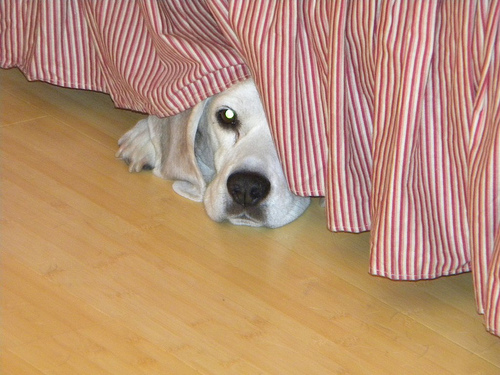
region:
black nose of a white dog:
[224, 166, 268, 206]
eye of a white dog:
[217, 104, 237, 125]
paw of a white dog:
[106, 114, 160, 179]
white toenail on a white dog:
[132, 155, 144, 174]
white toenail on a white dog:
[127, 158, 134, 174]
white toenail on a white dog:
[112, 142, 126, 159]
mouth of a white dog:
[221, 201, 270, 233]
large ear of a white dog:
[145, 95, 215, 207]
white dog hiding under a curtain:
[113, 58, 321, 233]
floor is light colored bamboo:
[2, 74, 497, 369]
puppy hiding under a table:
[119, 72, 321, 230]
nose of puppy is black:
[223, 160, 270, 210]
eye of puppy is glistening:
[213, 103, 244, 134]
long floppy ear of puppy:
[143, 96, 214, 206]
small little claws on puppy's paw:
[114, 115, 157, 177]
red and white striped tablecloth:
[0, 0, 498, 333]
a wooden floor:
[0, 63, 498, 374]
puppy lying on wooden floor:
[2, 54, 497, 374]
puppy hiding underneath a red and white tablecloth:
[2, 2, 499, 337]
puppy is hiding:
[108, 83, 331, 238]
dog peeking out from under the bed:
[96, 64, 326, 231]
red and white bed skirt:
[345, 26, 489, 266]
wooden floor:
[11, 171, 168, 316]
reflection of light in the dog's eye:
[215, 99, 239, 122]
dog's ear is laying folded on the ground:
[151, 146, 209, 209]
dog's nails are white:
[111, 133, 142, 178]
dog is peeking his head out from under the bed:
[113, 75, 305, 240]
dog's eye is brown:
[209, 105, 239, 132]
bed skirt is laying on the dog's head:
[172, 49, 289, 98]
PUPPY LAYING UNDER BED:
[104, 64, 317, 231]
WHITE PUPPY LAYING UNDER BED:
[109, 71, 315, 237]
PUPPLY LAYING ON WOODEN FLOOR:
[106, 67, 311, 233]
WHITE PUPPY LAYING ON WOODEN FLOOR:
[114, 77, 316, 233]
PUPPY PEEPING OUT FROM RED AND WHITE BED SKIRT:
[106, 77, 313, 232]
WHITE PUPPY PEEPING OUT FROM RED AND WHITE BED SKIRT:
[98, 76, 317, 231]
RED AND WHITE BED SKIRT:
[1, 1, 498, 339]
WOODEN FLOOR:
[1, 69, 498, 373]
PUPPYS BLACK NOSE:
[226, 169, 272, 205]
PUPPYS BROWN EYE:
[214, 104, 241, 131]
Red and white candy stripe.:
[339, 30, 452, 211]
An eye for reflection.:
[212, 104, 246, 139]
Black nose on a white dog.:
[211, 163, 276, 238]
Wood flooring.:
[46, 232, 246, 369]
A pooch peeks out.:
[103, 46, 334, 239]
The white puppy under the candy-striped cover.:
[110, 73, 339, 255]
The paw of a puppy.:
[112, 115, 164, 191]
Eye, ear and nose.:
[149, 104, 277, 211]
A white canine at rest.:
[109, 57, 331, 243]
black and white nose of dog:
[170, 150, 310, 245]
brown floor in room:
[61, 230, 195, 324]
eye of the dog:
[198, 89, 252, 134]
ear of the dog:
[123, 88, 234, 210]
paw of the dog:
[84, 110, 179, 203]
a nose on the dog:
[221, 157, 254, 199]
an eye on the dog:
[193, 84, 233, 129]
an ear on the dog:
[144, 73, 201, 154]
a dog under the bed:
[128, 28, 329, 213]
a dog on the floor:
[129, 33, 364, 257]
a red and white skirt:
[151, 5, 438, 185]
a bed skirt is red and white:
[319, 28, 484, 230]